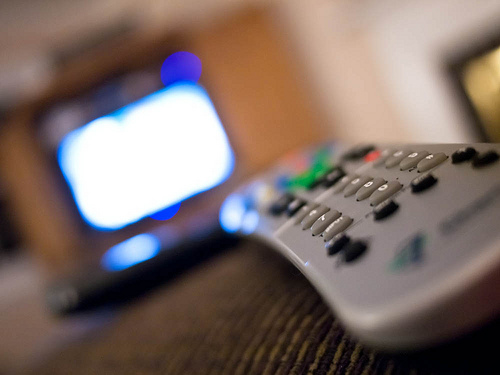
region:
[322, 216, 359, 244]
button on a remote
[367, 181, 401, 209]
button on a remote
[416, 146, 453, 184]
button on a remote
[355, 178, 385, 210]
button on a remote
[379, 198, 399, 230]
button on a remote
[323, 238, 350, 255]
button on a remote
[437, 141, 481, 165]
button on a remote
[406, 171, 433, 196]
button on a remote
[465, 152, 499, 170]
button on a remote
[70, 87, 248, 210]
the screen is on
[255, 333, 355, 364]
the couch is soft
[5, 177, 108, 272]
the wall is blurred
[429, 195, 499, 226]
logo on the remote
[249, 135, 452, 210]
buttons on the remote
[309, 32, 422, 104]
the wall is blurred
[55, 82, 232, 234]
A blurry, out of focus television screen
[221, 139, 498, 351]
A remote controller for a television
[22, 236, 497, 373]
A brown pillow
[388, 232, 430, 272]
The logo of the controller's manufacturer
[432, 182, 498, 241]
The name of the controller's manufacturer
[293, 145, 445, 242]
Numbers 0 through 9 on a remote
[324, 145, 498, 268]
Input buttons for various components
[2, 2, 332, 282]
A light brown entertainment system housing a television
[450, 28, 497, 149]
A fireplace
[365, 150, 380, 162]
The record button on the controller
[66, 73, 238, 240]
the TV is on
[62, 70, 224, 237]
the screen is blurry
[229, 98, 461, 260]
the remote is gray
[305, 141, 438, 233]
the buttons are gray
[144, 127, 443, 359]
remote is on a couch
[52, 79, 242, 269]
the TV is far away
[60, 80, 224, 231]
the light is blue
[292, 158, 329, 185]
the buttons are green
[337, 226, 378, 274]
button on a remote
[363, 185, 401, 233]
button on a remote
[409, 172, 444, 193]
button on a remote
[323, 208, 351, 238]
button on a remote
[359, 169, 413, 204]
button on a remote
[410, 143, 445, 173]
button on a remote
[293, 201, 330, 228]
button on a remote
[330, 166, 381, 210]
button on a remote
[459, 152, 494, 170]
button on a remote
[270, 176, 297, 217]
button on a remote